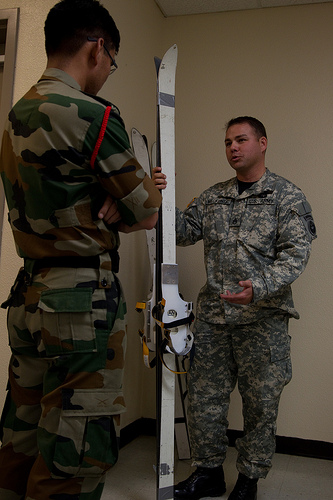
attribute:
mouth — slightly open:
[228, 153, 244, 162]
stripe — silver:
[154, 483, 182, 495]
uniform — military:
[177, 181, 315, 485]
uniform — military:
[5, 64, 159, 444]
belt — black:
[21, 253, 126, 274]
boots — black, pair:
[170, 462, 267, 494]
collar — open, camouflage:
[215, 172, 279, 199]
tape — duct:
[153, 88, 180, 106]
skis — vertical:
[128, 38, 200, 487]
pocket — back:
[36, 280, 101, 361]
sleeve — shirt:
[250, 186, 317, 309]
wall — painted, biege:
[147, 10, 315, 427]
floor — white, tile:
[96, 429, 329, 497]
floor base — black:
[122, 418, 328, 459]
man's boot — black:
[227, 471, 257, 498]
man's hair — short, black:
[223, 115, 267, 151]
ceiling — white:
[154, 0, 324, 15]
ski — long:
[152, 43, 198, 497]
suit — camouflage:
[177, 167, 317, 478]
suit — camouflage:
[0, 70, 162, 496]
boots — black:
[172, 465, 258, 496]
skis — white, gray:
[151, 41, 192, 498]